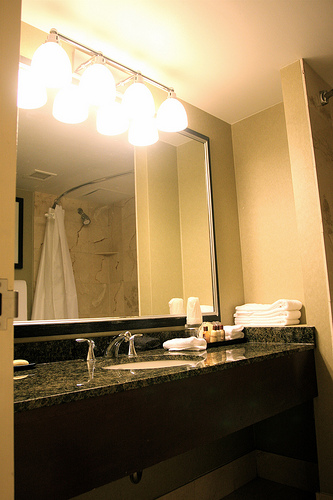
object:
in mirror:
[3, 119, 218, 324]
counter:
[0, 309, 316, 412]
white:
[240, 310, 280, 325]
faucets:
[104, 331, 132, 359]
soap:
[10, 355, 32, 367]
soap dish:
[10, 358, 38, 371]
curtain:
[32, 206, 80, 321]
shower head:
[76, 206, 92, 231]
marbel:
[65, 199, 134, 309]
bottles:
[203, 326, 211, 345]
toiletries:
[198, 326, 236, 343]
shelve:
[95, 247, 121, 259]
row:
[27, 14, 198, 141]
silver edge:
[204, 138, 216, 313]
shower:
[67, 197, 115, 290]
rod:
[47, 169, 134, 208]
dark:
[154, 371, 322, 498]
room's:
[5, 45, 314, 498]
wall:
[249, 84, 317, 287]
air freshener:
[186, 293, 203, 329]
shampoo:
[211, 331, 215, 341]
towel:
[161, 336, 209, 352]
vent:
[26, 168, 58, 182]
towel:
[232, 298, 303, 312]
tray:
[204, 336, 248, 348]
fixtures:
[74, 337, 97, 360]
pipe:
[125, 467, 185, 492]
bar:
[12, 356, 33, 369]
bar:
[49, 24, 176, 93]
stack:
[183, 294, 204, 329]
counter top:
[27, 308, 221, 359]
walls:
[44, 184, 142, 325]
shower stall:
[27, 185, 176, 317]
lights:
[156, 95, 191, 137]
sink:
[98, 354, 194, 373]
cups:
[185, 324, 201, 347]